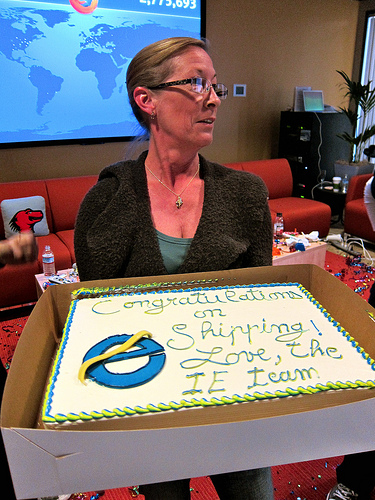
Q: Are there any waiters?
A: No, there are no waiters.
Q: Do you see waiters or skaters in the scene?
A: No, there are no waiters or skaters.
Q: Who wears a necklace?
A: The lady wears a necklace.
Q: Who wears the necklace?
A: The lady wears a necklace.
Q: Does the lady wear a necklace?
A: Yes, the lady wears a necklace.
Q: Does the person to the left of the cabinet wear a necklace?
A: Yes, the lady wears a necklace.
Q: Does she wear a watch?
A: No, the lady wears a necklace.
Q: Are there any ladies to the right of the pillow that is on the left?
A: Yes, there is a lady to the right of the pillow.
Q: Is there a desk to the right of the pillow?
A: No, there is a lady to the right of the pillow.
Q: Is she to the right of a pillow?
A: Yes, the lady is to the right of a pillow.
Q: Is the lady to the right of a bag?
A: No, the lady is to the right of a pillow.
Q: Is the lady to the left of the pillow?
A: No, the lady is to the right of the pillow.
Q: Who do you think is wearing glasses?
A: The lady is wearing glasses.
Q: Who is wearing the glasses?
A: The lady is wearing glasses.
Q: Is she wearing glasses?
A: Yes, the lady is wearing glasses.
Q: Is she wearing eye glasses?
A: No, the lady is wearing glasses.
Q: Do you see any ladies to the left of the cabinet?
A: Yes, there is a lady to the left of the cabinet.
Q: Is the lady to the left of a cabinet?
A: Yes, the lady is to the left of a cabinet.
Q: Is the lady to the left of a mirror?
A: No, the lady is to the left of a cabinet.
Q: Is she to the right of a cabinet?
A: No, the lady is to the left of a cabinet.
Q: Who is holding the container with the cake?
A: The lady is holding the box.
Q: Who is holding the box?
A: The lady is holding the box.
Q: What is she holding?
A: The lady is holding the box.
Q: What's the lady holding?
A: The lady is holding the box.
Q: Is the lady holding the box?
A: Yes, the lady is holding the box.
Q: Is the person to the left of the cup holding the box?
A: Yes, the lady is holding the box.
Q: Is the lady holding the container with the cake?
A: Yes, the lady is holding the box.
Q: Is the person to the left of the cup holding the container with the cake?
A: Yes, the lady is holding the box.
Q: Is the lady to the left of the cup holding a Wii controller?
A: No, the lady is holding the box.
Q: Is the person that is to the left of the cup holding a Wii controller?
A: No, the lady is holding the box.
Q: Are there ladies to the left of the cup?
A: Yes, there is a lady to the left of the cup.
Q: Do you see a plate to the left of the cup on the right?
A: No, there is a lady to the left of the cup.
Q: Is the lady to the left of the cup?
A: Yes, the lady is to the left of the cup.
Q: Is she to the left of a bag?
A: No, the lady is to the left of the cup.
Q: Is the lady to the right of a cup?
A: No, the lady is to the left of a cup.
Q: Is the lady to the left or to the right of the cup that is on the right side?
A: The lady is to the left of the cup.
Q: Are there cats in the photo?
A: No, there are no cats.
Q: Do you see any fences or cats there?
A: No, there are no cats or fences.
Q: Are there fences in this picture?
A: No, there are no fences.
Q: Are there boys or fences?
A: No, there are no fences or boys.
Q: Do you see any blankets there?
A: No, there are no blankets.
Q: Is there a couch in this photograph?
A: Yes, there is a couch.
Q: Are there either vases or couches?
A: Yes, there is a couch.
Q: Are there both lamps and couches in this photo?
A: No, there is a couch but no lamps.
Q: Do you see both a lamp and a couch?
A: No, there is a couch but no lamps.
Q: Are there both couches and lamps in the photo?
A: No, there is a couch but no lamps.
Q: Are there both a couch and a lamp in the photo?
A: No, there is a couch but no lamps.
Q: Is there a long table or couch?
A: Yes, there is a long couch.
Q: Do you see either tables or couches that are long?
A: Yes, the couch is long.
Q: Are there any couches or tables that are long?
A: Yes, the couch is long.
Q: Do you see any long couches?
A: Yes, there is a long couch.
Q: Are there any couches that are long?
A: Yes, there is a couch that is long.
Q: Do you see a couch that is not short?
A: Yes, there is a long couch.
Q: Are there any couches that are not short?
A: Yes, there is a long couch.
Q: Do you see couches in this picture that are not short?
A: Yes, there is a long couch.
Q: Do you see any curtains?
A: No, there are no curtains.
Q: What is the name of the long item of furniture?
A: The piece of furniture is a couch.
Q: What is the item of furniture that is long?
A: The piece of furniture is a couch.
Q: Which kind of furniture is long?
A: The furniture is a couch.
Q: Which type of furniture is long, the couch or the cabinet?
A: The couch is long.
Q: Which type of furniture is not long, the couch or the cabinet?
A: The cabinet is not long.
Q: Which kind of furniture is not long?
A: The furniture is a cabinet.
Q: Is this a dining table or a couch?
A: This is a couch.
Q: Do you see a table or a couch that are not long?
A: No, there is a couch but it is long.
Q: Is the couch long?
A: Yes, the couch is long.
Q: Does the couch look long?
A: Yes, the couch is long.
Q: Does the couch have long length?
A: Yes, the couch is long.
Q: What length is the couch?
A: The couch is long.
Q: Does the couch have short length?
A: No, the couch is long.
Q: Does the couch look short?
A: No, the couch is long.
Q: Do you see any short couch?
A: No, there is a couch but it is long.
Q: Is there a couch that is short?
A: No, there is a couch but it is long.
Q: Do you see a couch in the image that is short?
A: No, there is a couch but it is long.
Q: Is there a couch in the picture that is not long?
A: No, there is a couch but it is long.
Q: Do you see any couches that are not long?
A: No, there is a couch but it is long.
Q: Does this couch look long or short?
A: The couch is long.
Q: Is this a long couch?
A: Yes, this is a long couch.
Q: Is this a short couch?
A: No, this is a long couch.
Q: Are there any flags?
A: No, there are no flags.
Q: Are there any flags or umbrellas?
A: No, there are no flags or umbrellas.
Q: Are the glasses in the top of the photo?
A: Yes, the glasses are in the top of the image.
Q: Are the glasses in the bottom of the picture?
A: No, the glasses are in the top of the image.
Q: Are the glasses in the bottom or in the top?
A: The glasses are in the top of the image.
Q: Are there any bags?
A: No, there are no bags.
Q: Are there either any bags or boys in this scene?
A: No, there are no bags or boys.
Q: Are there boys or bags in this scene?
A: No, there are no bags or boys.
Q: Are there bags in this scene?
A: No, there are no bags.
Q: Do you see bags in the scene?
A: No, there are no bags.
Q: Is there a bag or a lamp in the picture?
A: No, there are no bags or lamps.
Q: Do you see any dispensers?
A: No, there are no dispensers.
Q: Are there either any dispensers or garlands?
A: No, there are no dispensers or garlands.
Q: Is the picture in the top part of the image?
A: Yes, the picture is in the top of the image.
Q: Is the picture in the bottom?
A: No, the picture is in the top of the image.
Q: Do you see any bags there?
A: No, there are no bags.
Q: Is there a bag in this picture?
A: No, there are no bags.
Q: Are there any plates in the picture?
A: No, there are no plates.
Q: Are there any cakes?
A: Yes, there is a cake.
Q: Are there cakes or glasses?
A: Yes, there is a cake.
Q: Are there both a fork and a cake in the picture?
A: No, there is a cake but no forks.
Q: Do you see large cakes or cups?
A: Yes, there is a large cake.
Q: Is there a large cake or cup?
A: Yes, there is a large cake.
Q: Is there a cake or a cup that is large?
A: Yes, the cake is large.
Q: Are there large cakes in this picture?
A: Yes, there is a large cake.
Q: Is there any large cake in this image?
A: Yes, there is a large cake.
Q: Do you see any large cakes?
A: Yes, there is a large cake.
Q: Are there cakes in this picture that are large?
A: Yes, there is a cake that is large.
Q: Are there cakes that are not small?
A: Yes, there is a large cake.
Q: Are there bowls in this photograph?
A: No, there are no bowls.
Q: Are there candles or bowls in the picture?
A: No, there are no bowls or candles.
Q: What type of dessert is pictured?
A: The dessert is a cake.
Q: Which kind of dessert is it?
A: The dessert is a cake.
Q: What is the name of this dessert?
A: This is a cake.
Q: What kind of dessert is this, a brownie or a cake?
A: This is a cake.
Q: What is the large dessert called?
A: The dessert is a cake.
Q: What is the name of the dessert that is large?
A: The dessert is a cake.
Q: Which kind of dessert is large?
A: The dessert is a cake.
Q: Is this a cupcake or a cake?
A: This is a cake.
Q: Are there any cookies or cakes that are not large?
A: No, there is a cake but it is large.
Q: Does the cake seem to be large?
A: Yes, the cake is large.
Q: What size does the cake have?
A: The cake has large size.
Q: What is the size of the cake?
A: The cake is large.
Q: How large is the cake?
A: The cake is large.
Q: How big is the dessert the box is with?
A: The cake is large.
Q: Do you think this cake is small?
A: No, the cake is large.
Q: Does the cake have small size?
A: No, the cake is large.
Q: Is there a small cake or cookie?
A: No, there is a cake but it is large.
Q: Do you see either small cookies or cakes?
A: No, there is a cake but it is large.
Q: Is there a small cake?
A: No, there is a cake but it is large.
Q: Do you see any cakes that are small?
A: No, there is a cake but it is large.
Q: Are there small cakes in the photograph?
A: No, there is a cake but it is large.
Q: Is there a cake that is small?
A: No, there is a cake but it is large.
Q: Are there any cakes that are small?
A: No, there is a cake but it is large.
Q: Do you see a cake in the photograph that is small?
A: No, there is a cake but it is large.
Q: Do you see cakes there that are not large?
A: No, there is a cake but it is large.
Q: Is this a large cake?
A: Yes, this is a large cake.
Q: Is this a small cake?
A: No, this is a large cake.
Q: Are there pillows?
A: Yes, there is a pillow.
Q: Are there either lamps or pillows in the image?
A: Yes, there is a pillow.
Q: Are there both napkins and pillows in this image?
A: No, there is a pillow but no napkins.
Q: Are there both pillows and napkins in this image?
A: No, there is a pillow but no napkins.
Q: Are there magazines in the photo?
A: No, there are no magazines.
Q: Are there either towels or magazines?
A: No, there are no magazines or towels.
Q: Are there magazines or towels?
A: No, there are no magazines or towels.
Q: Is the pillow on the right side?
A: No, the pillow is on the left of the image.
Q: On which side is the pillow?
A: The pillow is on the left of the image.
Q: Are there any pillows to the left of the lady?
A: Yes, there is a pillow to the left of the lady.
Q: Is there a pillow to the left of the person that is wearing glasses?
A: Yes, there is a pillow to the left of the lady.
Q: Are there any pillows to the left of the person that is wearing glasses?
A: Yes, there is a pillow to the left of the lady.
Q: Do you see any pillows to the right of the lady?
A: No, the pillow is to the left of the lady.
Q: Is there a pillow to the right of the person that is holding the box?
A: No, the pillow is to the left of the lady.